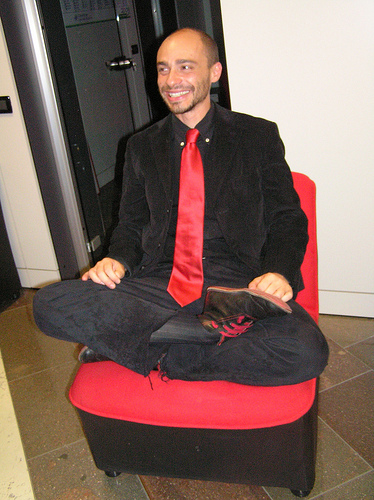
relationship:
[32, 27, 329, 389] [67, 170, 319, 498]
man sitting on chair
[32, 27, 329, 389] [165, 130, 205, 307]
man wearing tie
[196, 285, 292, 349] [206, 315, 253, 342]
shoe has shoelaces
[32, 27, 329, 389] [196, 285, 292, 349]
man wearing shoe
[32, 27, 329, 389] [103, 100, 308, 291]
man wearing jacket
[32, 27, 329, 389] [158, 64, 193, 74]
man has eyes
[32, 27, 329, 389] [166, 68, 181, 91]
man has nose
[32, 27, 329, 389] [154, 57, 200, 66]
man has eyebrows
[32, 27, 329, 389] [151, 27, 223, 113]
man has head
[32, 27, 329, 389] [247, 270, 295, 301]
man has left hand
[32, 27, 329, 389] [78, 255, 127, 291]
man has right hand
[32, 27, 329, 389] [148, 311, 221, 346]
man wearing sock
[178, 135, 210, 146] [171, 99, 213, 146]
buttons on top of collar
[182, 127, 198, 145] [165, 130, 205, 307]
knot on top of tie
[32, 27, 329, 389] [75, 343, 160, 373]
man wearing shoe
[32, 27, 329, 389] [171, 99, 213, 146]
man has collar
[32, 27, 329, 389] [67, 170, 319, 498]
man sitting in chair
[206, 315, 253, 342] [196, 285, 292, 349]
shoelaces on top of shoe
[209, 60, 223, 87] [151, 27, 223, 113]
ear attached to head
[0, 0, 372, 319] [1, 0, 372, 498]
wall inside of room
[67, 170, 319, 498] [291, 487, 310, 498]
chair has front foot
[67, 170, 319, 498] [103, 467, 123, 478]
chair has front foot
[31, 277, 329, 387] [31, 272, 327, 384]
legs wearing pants